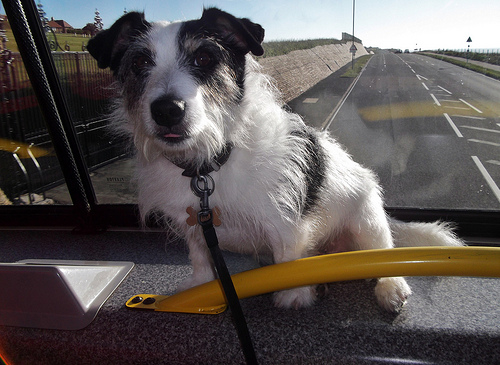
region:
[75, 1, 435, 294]
This is a dog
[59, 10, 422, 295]
The dog is in a vehicle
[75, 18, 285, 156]
The dog is looking at the camera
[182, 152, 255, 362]
Dog is wearing a leash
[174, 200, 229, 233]
A bone shaped dog tag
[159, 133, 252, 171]
The dog is wearing a collar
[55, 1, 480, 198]
Large window in the back of the vehicle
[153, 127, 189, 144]
Dog's tongue sticking out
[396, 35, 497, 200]
White lines on the road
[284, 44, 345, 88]
A wall made of stone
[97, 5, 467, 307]
Black and white dog in car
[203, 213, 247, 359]
Black leash on dog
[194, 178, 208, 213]
Metal clip on leash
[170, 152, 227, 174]
Black collar around dog's neck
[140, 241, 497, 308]
Yellow metal handle support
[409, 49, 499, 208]
White lines on road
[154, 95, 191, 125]
Large black dog nose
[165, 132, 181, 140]
Tip of dog's tongue sticking out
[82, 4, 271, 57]
Floppy black ears on dog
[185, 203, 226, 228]
Bone shaped dog tag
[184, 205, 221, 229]
a metal dog bone dog tag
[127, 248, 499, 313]
a yellow hand rail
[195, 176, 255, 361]
a black dog leash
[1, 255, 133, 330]
a gray speaker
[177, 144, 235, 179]
a black collar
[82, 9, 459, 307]
a dog sitting on the dashboard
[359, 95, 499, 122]
reflection on the window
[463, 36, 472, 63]
street sign on a post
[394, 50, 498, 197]
white painted lines on the asphalt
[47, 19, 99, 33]
large house in the distance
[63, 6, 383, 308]
a dog with a leash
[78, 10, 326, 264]
a dog with a leash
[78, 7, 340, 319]
a dog with a leash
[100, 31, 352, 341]
a dog with a leash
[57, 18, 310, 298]
a dog with a leash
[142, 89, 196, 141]
dog's nose is black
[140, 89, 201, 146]
dog's nose is black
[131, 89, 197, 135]
dog's nose is black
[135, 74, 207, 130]
dog's nose is black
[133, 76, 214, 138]
dog's nose is black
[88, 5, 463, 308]
a white and black dog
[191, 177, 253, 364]
a black leash attached to a dog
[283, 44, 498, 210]
a highway behind the window of a car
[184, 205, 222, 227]
a dog tag shaped like a bone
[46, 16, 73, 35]
a house with a brown roof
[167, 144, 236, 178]
a dog black collar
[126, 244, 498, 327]
a yellow metal handle in the back of a car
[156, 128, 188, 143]
a dog sticking out its tongue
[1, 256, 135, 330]
a gray speaker in the back of a car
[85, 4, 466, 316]
a black and white dog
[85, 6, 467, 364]
black leash is connected to dog's collar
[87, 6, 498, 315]
yellow curving bar in front of dog's feet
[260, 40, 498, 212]
sloping wall bordering road